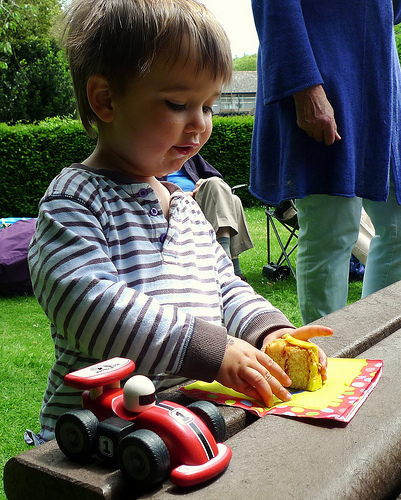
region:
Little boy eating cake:
[25, 1, 277, 403]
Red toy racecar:
[47, 344, 238, 491]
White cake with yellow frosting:
[257, 328, 337, 400]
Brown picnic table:
[231, 426, 399, 498]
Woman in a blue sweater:
[237, 0, 400, 303]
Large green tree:
[3, 0, 69, 123]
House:
[232, 67, 258, 113]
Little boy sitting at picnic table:
[31, 1, 280, 381]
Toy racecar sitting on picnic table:
[45, 347, 240, 492]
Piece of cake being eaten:
[259, 330, 334, 394]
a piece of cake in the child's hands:
[256, 331, 323, 394]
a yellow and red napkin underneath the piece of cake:
[178, 351, 389, 423]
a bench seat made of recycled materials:
[2, 251, 400, 496]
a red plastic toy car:
[48, 349, 236, 493]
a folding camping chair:
[251, 189, 326, 285]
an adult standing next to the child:
[246, 1, 400, 324]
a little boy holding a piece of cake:
[27, 1, 335, 466]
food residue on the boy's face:
[157, 148, 185, 168]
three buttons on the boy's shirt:
[136, 187, 170, 246]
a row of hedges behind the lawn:
[0, 109, 288, 219]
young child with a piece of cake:
[32, 2, 336, 428]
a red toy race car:
[54, 352, 237, 490]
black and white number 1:
[95, 431, 116, 458]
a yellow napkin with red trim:
[166, 355, 380, 429]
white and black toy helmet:
[119, 369, 160, 412]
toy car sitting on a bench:
[5, 335, 285, 497]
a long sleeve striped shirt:
[27, 158, 303, 381]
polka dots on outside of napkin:
[170, 359, 400, 423]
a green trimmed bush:
[3, 109, 259, 231]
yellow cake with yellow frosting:
[260, 339, 330, 392]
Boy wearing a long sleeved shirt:
[29, 159, 297, 441]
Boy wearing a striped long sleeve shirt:
[20, 159, 304, 446]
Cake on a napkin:
[179, 332, 384, 424]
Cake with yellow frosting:
[252, 328, 324, 391]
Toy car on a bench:
[56, 351, 233, 489]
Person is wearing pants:
[291, 173, 398, 331]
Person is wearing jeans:
[289, 178, 391, 329]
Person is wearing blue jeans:
[291, 178, 394, 340]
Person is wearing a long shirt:
[243, 1, 399, 210]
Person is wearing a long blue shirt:
[246, 0, 396, 209]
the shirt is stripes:
[32, 162, 272, 387]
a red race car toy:
[75, 338, 193, 490]